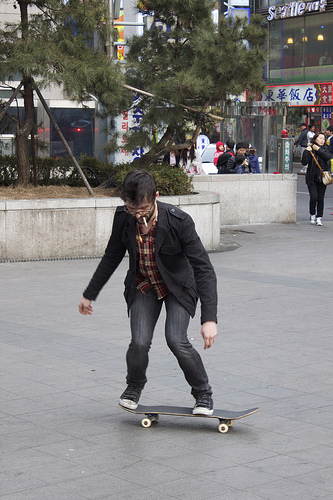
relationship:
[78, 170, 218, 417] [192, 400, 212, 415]
man wearing shoe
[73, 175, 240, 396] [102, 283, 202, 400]
man wearing jeans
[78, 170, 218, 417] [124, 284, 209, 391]
man wearing jeans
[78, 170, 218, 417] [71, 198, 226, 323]
man wearing coat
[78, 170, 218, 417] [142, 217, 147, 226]
man has cigarette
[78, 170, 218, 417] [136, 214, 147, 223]
man has mouth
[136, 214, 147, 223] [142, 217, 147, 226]
mouth has cigarette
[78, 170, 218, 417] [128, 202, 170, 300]
man wearing shirt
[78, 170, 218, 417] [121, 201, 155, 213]
man wearing glasses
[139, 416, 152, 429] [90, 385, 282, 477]
wheel underneath skateboard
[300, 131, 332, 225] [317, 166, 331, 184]
women wearing purse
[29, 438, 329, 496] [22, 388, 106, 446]
pavement made of cement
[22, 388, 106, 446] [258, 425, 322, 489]
cement on top of ground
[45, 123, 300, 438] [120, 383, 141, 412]
skateboarder wearing shoe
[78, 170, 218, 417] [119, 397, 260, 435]
man riding on skateboard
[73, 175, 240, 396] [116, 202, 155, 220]
man wearing glasses